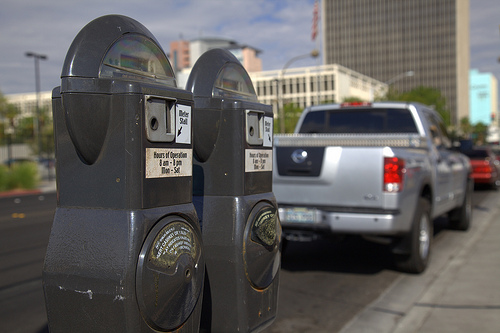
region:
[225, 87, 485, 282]
The truck is on the street.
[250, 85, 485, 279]
The truck is silver.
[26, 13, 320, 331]
Two parking meters are side by side.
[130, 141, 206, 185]
The hours of operation are on the meter.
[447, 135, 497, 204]
A vehicle is in front of the truck.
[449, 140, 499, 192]
The vehicle is red.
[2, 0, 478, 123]
Buildings are in the background.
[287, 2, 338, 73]
An American flag is on the building.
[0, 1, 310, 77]
Clouds are in the sky.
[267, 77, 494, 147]
Trees are in the background.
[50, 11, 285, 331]
Two parking meters next to each other.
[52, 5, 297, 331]
The meters are grey.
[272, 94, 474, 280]
The truck is parked.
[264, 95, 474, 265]
The truck is silver.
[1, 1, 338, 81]
The sky is blue.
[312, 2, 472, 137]
Tall building in background.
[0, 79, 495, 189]
The trees are green.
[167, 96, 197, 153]
the sticker is white.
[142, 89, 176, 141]
Spot for parking change.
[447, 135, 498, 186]
The car is red.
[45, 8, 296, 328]
Two gray City meters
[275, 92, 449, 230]
The back of a silver truck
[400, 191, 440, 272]
a black rear tire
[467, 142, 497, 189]
The back of a parked red car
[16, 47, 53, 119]
a lamp post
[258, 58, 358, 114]
a white building with windows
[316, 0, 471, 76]
A slate colored office building with many windows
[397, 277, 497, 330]
The sidewalk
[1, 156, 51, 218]
green plant on a clay planter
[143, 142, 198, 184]
hours of operation sign on the meter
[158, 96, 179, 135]
a coin slot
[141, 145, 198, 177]
a white sticker on the parking meter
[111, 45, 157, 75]
the parking meter readout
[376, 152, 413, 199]
the tail light of the truck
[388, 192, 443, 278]
the black tire of the truck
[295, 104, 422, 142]
the rear window of the truck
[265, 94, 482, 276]
a gray truck on the road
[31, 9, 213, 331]
a gray metal parking meter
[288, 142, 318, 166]
a logo on the truck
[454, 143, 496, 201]
a red car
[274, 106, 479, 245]
silver pick up truck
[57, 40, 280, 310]
black parking meter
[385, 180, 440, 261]
back tire on silver truck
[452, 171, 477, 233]
front tire on silver truck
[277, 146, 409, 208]
tale gate on silver truck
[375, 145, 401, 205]
tale light on silver truck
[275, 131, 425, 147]
toolbox on silver truck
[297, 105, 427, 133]
back window of silver truck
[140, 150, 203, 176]
hour of operation on parking meter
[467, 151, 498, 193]
red vehicle in front of silver truck